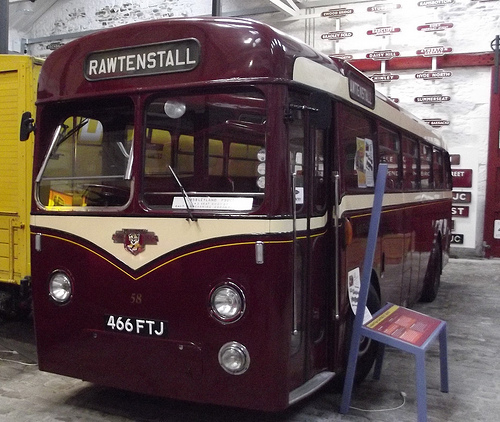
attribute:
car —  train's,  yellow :
[0, 52, 257, 286]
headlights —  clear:
[212, 336, 254, 379]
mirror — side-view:
[19, 108, 34, 145]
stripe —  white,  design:
[30, 188, 454, 270]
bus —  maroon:
[4, 12, 474, 394]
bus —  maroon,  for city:
[32, 17, 486, 416]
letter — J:
[152, 317, 167, 338]